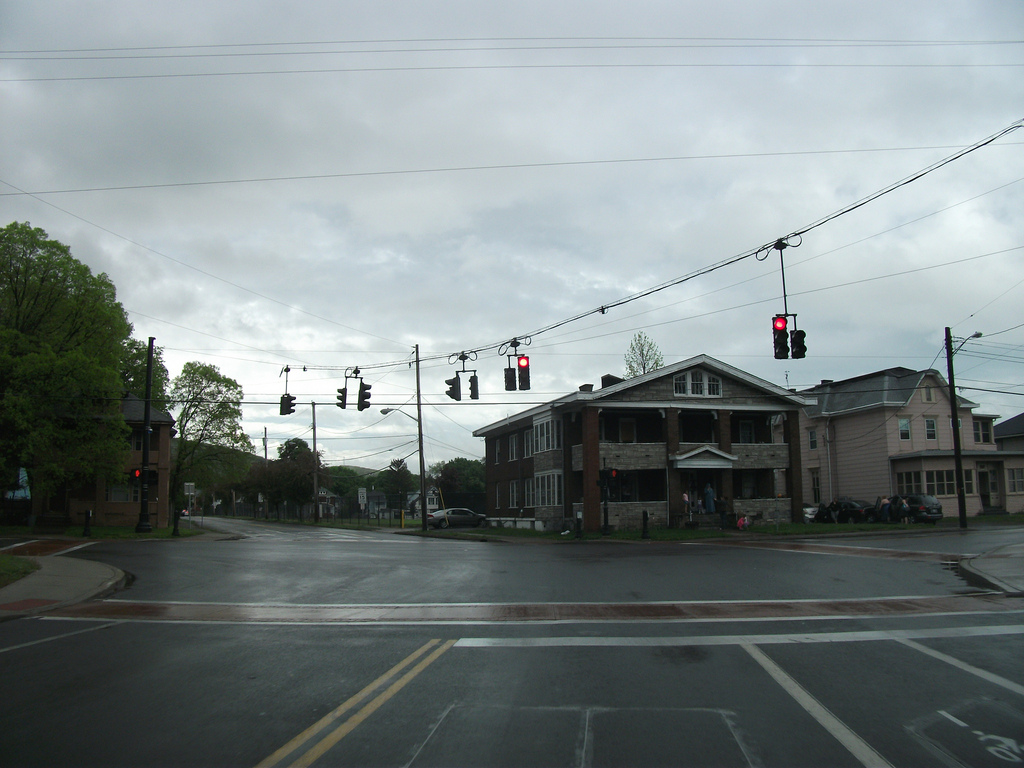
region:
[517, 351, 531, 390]
traffic light is hanging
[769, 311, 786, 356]
traffic light is hanging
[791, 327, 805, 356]
traffic light is hanging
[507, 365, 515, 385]
traffic light is hanging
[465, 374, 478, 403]
traffic light is hanging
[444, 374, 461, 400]
traffic light is hanging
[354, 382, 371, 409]
traffic light is hanging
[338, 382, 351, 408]
traffic light is hanging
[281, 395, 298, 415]
traffic light is hanging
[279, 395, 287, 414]
traffic light is hanging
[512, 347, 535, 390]
traffic light hanging from the wire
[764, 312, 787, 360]
traffic light hanging from the wire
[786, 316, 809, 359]
traffic light hanging from the wire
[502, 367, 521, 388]
traffic light hanging from the wire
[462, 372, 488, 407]
traffic light hanging from the wire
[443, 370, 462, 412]
traffic light hanging from the wire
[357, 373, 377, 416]
traffic light hanging from the wire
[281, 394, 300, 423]
traffic light hanging from the wire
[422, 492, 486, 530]
car parked in the driveway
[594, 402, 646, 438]
Window on the house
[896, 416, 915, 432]
Window on the house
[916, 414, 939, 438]
Window on the house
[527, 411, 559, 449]
Window on the house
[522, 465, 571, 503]
Window on the house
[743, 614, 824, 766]
white line painted on the street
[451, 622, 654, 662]
white line painted on the street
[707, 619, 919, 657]
white line painted on the street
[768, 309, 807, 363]
the red traffic light hanging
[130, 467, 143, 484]
the crosswalk signal on the sign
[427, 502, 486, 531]
the car parked in the driveway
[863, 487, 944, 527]
the van parked in the driveway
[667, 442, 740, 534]
the front porch of the house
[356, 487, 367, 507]
the white speed limit sign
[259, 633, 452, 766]
the double yellow line on the road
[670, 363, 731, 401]
the window on the attic of the old house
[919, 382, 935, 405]
the highest window on the pink house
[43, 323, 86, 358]
green leaves on the tree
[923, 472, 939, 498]
glass window on the building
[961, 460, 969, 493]
glass window on the building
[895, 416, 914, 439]
glass window on the building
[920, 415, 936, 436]
glass window on the building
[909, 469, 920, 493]
glass window on the building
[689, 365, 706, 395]
glass window on the building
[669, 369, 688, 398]
glass window on the building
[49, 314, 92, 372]
green leaves on the tree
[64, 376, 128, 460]
green leaves on the tree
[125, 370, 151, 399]
green leaves on the tree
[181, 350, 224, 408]
green leaves on the tree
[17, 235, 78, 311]
green leaves on the tree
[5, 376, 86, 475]
green leaves on the tree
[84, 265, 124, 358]
green leaves on the tree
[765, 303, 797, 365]
right traffic light is red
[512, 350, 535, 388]
middle traffic light is red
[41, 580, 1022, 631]
cross walk between sidewalks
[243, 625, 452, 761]
double yellow lines on road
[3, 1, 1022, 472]
sky is mostly cloudy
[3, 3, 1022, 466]
sky is mostly gray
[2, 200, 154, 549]
large tree behind sidewalk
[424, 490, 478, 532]
car parked by building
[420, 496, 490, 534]
parked car is small